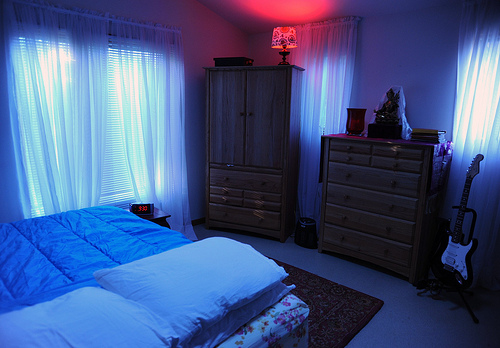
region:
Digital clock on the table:
[118, 195, 172, 227]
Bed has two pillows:
[3, 195, 315, 346]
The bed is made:
[1, 200, 311, 346]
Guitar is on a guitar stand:
[403, 126, 498, 329]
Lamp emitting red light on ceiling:
[237, 0, 335, 69]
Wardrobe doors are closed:
[193, 18, 313, 260]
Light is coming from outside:
[0, 3, 211, 247]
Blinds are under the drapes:
[1, 2, 210, 247]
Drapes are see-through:
[1, 1, 210, 251]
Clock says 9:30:
[129, 199, 156, 222]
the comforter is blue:
[19, 209, 149, 260]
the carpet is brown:
[303, 272, 390, 337]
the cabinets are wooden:
[321, 134, 436, 271]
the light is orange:
[266, 17, 302, 47]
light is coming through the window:
[28, 42, 173, 194]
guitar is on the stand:
[431, 176, 478, 291]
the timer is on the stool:
[133, 202, 155, 213]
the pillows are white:
[133, 259, 273, 320]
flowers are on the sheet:
[253, 300, 300, 342]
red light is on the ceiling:
[262, 7, 320, 25]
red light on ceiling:
[231, 0, 346, 30]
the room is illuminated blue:
[5, 5, 496, 345]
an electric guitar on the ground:
[435, 140, 495, 305]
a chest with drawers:
[310, 120, 455, 290]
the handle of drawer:
[340, 145, 355, 155]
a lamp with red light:
[260, 15, 310, 75]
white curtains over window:
[1, 7, 207, 220]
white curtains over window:
[442, 6, 494, 178]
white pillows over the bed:
[3, 221, 295, 346]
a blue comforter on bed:
[0, 200, 197, 312]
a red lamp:
[272, 27, 303, 67]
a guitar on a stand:
[429, 156, 487, 311]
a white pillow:
[105, 236, 287, 323]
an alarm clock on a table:
[129, 198, 175, 230]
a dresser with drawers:
[310, 131, 435, 283]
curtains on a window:
[6, 7, 194, 220]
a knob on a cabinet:
[246, 110, 253, 119]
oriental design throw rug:
[272, 246, 385, 346]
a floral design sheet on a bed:
[218, 296, 310, 346]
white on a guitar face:
[437, 233, 477, 285]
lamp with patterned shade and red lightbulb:
[268, 24, 298, 66]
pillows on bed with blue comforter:
[0, 234, 294, 346]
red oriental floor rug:
[260, 253, 384, 347]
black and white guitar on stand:
[416, 152, 485, 321]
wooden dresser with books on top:
[313, 129, 453, 279]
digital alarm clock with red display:
[127, 202, 153, 215]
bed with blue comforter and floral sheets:
[0, 207, 311, 347]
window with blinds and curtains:
[3, 8, 195, 240]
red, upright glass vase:
[344, 106, 366, 137]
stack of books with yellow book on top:
[407, 128, 446, 143]